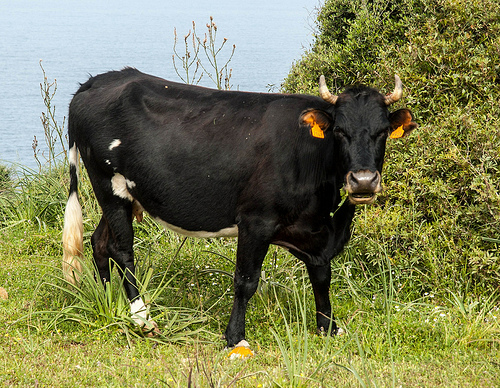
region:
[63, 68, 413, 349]
a black and white bull grazing in the grass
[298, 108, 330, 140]
the bulls ears are tagged for identification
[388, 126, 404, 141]
an orange id tag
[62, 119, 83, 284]
the bulls tail has white hair at the end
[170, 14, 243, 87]
wild flower buds are on the tree behind the bull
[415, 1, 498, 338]
thick brush next to the bull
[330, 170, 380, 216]
the bulls mouth is full of grass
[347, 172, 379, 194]
the bulls nose is a grey color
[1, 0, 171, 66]
a blue stream is next to the field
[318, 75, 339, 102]
the bulls horns are white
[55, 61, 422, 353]
The cow in the photo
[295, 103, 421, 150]
The ears of the cow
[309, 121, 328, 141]
The tag in the right ear of the dog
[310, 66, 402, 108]
The horns of the cow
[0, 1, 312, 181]
The body of water behind the cow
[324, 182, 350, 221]
The grass hanging out of the cows mouth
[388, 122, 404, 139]
The tag in the left ear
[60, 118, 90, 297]
The cow's tail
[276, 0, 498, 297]
The bush to the right of the cow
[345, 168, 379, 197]
The nose of the cow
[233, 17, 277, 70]
part of a water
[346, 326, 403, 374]
part of some grass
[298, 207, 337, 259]
part of a chest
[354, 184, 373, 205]
mouth of a cow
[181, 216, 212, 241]
part of a stomach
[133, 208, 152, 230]
part of an udder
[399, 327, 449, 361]
part of some grass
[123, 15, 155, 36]
part of a water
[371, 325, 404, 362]
part of a grass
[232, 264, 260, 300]
part of a knee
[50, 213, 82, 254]
part of a tail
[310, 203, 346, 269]
part of a chest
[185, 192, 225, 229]
part of a stomach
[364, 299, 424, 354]
part of a grass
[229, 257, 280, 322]
part of a knee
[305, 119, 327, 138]
Orange tag on a cow's ear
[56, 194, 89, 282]
Cow's white tail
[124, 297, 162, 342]
White spot on a cows foot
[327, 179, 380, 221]
Cow's mouth chewing grass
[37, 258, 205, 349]
Grass in a field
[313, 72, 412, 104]
White horns on a cow's head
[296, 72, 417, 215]
Cow's head looking forward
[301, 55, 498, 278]
Trees behind a cow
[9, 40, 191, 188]
Water behind a cow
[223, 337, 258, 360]
Yellow tag on a cow's hoof